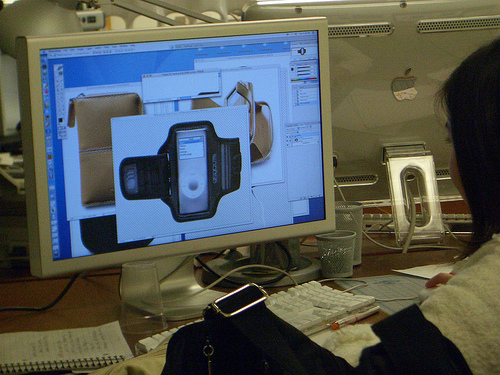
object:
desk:
[0, 198, 500, 374]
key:
[308, 301, 334, 323]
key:
[327, 302, 351, 319]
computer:
[23, 13, 388, 352]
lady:
[320, 34, 499, 375]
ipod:
[166, 118, 224, 230]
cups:
[316, 224, 360, 283]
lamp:
[43, 0, 283, 43]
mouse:
[418, 279, 443, 303]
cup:
[116, 269, 173, 335]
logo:
[391, 71, 421, 104]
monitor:
[16, 29, 332, 258]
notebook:
[0, 315, 127, 372]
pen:
[326, 304, 384, 331]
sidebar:
[12, 51, 93, 289]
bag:
[157, 274, 347, 375]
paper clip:
[317, 233, 356, 278]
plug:
[71, 6, 107, 32]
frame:
[21, 14, 349, 289]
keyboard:
[140, 281, 372, 369]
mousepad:
[335, 264, 434, 312]